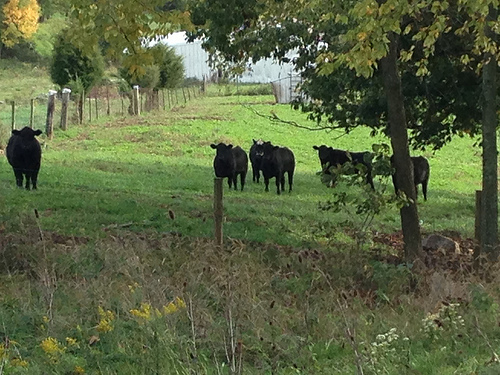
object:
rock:
[422, 233, 457, 253]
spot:
[256, 139, 264, 146]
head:
[252, 139, 266, 156]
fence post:
[213, 176, 224, 245]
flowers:
[374, 333, 385, 341]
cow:
[4, 125, 42, 191]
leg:
[233, 174, 238, 190]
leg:
[240, 172, 247, 192]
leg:
[227, 174, 233, 190]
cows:
[311, 144, 376, 193]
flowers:
[154, 305, 163, 319]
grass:
[0, 57, 500, 375]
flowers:
[96, 318, 113, 333]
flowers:
[128, 284, 134, 290]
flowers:
[402, 336, 410, 342]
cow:
[209, 142, 248, 192]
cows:
[259, 140, 296, 196]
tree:
[0, 0, 43, 41]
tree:
[176, 0, 482, 266]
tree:
[50, 27, 104, 124]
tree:
[119, 49, 156, 69]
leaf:
[24, 26, 28, 29]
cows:
[248, 137, 268, 184]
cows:
[388, 152, 430, 203]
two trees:
[157, 0, 500, 269]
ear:
[312, 145, 318, 150]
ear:
[210, 143, 217, 150]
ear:
[35, 128, 42, 136]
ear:
[12, 128, 20, 136]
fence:
[269, 74, 333, 104]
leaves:
[360, 65, 370, 79]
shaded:
[0, 156, 477, 244]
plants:
[194, 216, 255, 375]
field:
[0, 56, 500, 375]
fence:
[0, 72, 208, 147]